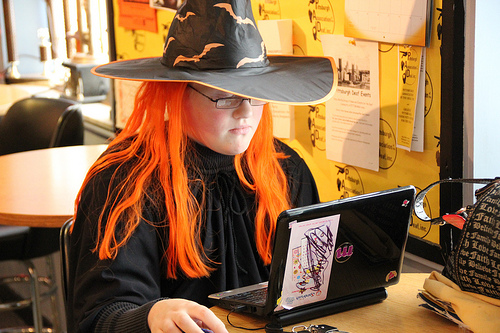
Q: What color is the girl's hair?
A: Orange.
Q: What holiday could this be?
A: Halloween.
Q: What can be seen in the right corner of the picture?
A: Half a black purse with writing on it.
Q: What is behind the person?
A: A bulletin board with a yellow background.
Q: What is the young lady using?
A: A laptop.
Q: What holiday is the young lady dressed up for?
A: Halloween.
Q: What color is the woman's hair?
A: Orange.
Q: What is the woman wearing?
A: A witch's hat.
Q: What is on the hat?
A: Bats.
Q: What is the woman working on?
A: A laptop.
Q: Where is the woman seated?
A: In a cafe.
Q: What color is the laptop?
A: Black.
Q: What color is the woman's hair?
A: Orange.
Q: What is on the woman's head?
A: Witches hat.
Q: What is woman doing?
A: Using laptop.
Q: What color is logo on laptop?
A: Pink.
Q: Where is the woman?
A: At a table.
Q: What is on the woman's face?
A: Glasses.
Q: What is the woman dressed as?
A: A witch.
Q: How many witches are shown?
A: One.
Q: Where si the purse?
A: On the table.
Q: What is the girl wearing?
A: A witch costume.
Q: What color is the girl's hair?
A: Orange.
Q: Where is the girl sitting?
A: At a table.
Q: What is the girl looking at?
A: A laptop.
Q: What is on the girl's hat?
A: Orange bats.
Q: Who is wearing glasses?
A: The girl.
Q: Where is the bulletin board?
A: On the wall behind the girl.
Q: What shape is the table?
A: Round.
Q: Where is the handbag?
A: On the table.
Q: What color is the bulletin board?
A: Yellow.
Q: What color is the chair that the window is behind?
A: Black.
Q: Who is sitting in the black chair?
A: No one.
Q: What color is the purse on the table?
A: Black and white.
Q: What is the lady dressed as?
A: A Witch.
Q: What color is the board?
A: Yellow.